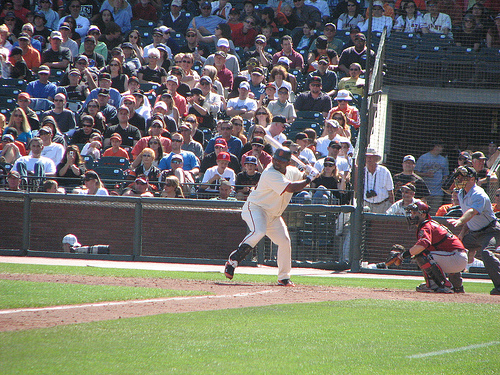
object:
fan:
[159, 131, 201, 174]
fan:
[103, 104, 142, 146]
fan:
[71, 115, 101, 145]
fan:
[82, 72, 120, 108]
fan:
[152, 75, 187, 114]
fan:
[227, 81, 258, 118]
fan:
[265, 84, 298, 122]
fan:
[293, 75, 332, 116]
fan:
[267, 65, 293, 99]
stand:
[0, 7, 376, 275]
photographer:
[60, 233, 82, 254]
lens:
[97, 244, 112, 254]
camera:
[69, 244, 111, 254]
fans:
[100, 135, 130, 173]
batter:
[224, 145, 322, 288]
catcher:
[385, 198, 468, 293]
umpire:
[445, 164, 500, 295]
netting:
[361, 46, 500, 274]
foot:
[223, 259, 236, 280]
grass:
[264, 308, 378, 362]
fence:
[0, 188, 355, 271]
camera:
[366, 189, 378, 198]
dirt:
[281, 291, 476, 301]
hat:
[366, 147, 382, 162]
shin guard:
[228, 242, 256, 267]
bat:
[261, 133, 305, 169]